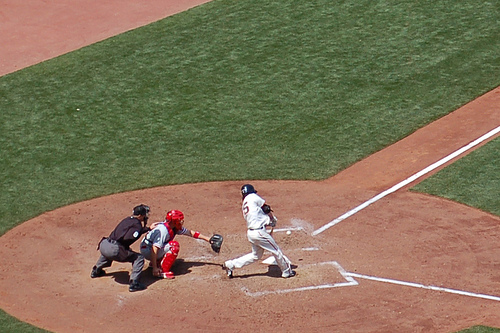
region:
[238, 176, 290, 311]
Baseball player at bat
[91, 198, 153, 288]
Umpire preparing to make call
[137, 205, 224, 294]
Baseball player ready to catch ball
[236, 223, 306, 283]
Home plate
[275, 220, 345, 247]
The throw looks like a strike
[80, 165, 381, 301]
Baseball game at play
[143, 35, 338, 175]
Green grass of baseball field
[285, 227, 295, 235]
Baseball flying over plate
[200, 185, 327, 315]
Right handed batter in box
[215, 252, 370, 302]
Batter in Batter's box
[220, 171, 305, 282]
A baseball player hitting the baseball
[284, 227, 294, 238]
A white baseball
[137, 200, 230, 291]
A catcher wearing red gear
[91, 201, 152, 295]
A baseball umpire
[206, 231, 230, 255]
A baseball catcher's mitt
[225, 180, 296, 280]
A baseball uniform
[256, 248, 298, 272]
A baseball home base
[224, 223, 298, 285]
White baseball uniform's pants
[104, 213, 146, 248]
A black shirt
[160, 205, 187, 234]
A red protective catcher's helmet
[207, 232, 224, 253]
catcher's mitt on left hand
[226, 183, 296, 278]
baseball player about to hit baseball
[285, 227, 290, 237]
baseball in the air above home base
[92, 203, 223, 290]
umpire behind catcher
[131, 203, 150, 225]
umpire has face mask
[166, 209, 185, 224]
catcher's has red helmet on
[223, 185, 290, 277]
batter has number five on back of his shirt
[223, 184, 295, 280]
batter is about to hit baseball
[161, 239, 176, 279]
catcher has red shin guards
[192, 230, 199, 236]
catcher had red arm band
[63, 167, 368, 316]
People playing baseball on field.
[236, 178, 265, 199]
Batter wearing black helmet.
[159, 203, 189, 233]
Catcher wearing red helmet.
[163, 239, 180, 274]
Catcher wearing red knee and shin guards.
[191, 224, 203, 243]
Catcher wearing red armband.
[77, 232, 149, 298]
Umpire wearing gray pants.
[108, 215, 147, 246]
Umpire wearing black shirt.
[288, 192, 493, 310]
White markings on baseball diamond.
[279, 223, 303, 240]
White baseball in front of batter.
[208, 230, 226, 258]
Catcher wearing baseball mitt on left hand.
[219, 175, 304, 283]
A baseball player hitting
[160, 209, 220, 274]
A baseball catcher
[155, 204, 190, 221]
A red baseball catcher helmet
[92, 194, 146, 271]
A baseball umpire in action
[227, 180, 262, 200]
A black helmet of a baseball player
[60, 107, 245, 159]
The green baseball field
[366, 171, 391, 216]
The white painted line for the baseball game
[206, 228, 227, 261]
A black baseball catcher glove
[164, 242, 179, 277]
A red baseball catcher knee protector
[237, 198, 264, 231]
A player uniform top with Number 5